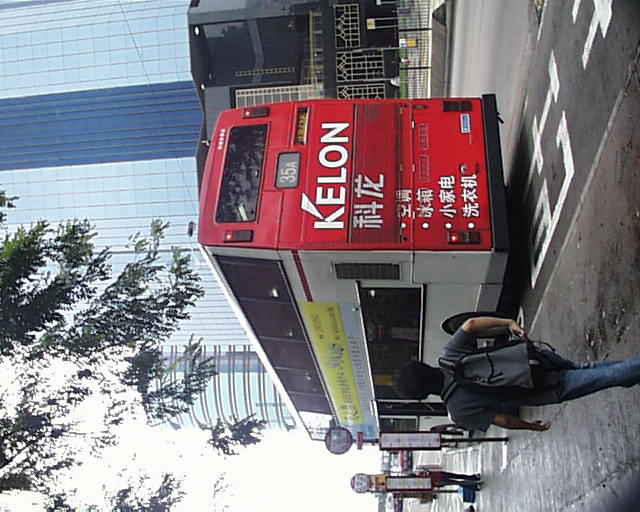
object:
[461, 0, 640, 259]
road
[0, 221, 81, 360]
leaves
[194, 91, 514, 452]
bus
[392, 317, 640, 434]
man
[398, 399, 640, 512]
sidewalk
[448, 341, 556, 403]
bagpack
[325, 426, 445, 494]
sign board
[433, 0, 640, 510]
sidewalk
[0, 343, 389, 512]
sky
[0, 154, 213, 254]
wall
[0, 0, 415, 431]
building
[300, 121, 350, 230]
text